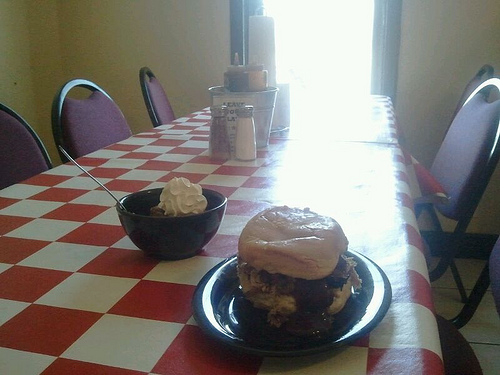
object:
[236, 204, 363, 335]
food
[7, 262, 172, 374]
table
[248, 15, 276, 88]
paper towels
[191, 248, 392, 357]
plate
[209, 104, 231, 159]
shakers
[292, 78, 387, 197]
sunlight